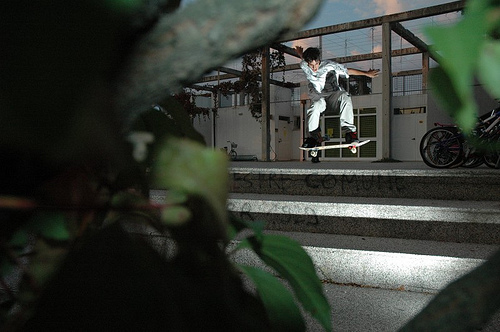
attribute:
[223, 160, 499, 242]
steps — grey 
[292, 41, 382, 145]
boy — skateboarding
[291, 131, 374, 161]
board — skating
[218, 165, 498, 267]
gray stairs — grey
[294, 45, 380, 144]
person — skating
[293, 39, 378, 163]
skateboarder — performing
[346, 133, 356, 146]
shoe — black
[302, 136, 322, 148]
shoe — black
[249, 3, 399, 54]
fencing — metal 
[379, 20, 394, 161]
metal pole — tall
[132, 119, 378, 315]
leaves — green 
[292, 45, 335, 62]
hair — dark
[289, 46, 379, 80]
arms — up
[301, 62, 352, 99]
shirt — white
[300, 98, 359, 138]
pants — man's pants, white